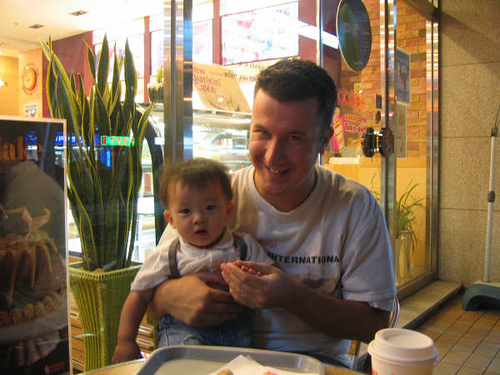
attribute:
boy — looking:
[140, 161, 280, 339]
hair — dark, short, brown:
[164, 160, 227, 180]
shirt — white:
[128, 233, 271, 274]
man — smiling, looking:
[209, 40, 421, 374]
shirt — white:
[230, 164, 402, 359]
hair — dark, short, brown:
[265, 53, 324, 104]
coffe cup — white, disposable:
[361, 316, 442, 373]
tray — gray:
[142, 343, 323, 373]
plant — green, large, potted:
[43, 43, 146, 289]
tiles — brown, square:
[470, 329, 493, 363]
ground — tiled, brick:
[416, 284, 499, 373]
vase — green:
[65, 254, 133, 367]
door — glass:
[329, 1, 449, 288]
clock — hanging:
[19, 64, 39, 91]